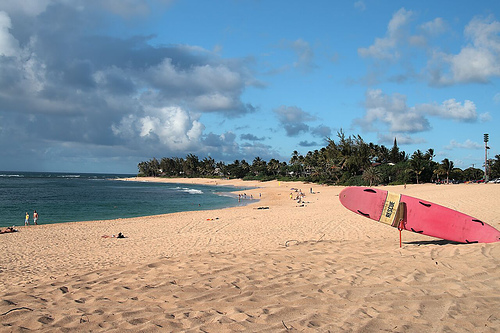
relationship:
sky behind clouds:
[168, 2, 385, 60] [76, 41, 213, 140]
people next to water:
[19, 208, 40, 226] [0, 176, 262, 229]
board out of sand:
[337, 186, 500, 244] [1, 175, 499, 332]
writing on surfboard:
[382, 193, 399, 219] [337, 178, 497, 261]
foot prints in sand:
[2, 257, 497, 332] [1, 175, 499, 332]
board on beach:
[337, 186, 500, 244] [18, 169, 497, 333]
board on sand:
[337, 186, 500, 244] [1, 175, 499, 332]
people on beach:
[288, 183, 306, 210] [206, 190, 351, 262]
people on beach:
[18, 207, 39, 224] [18, 169, 497, 333]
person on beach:
[2, 224, 18, 238] [10, 170, 11, 171]